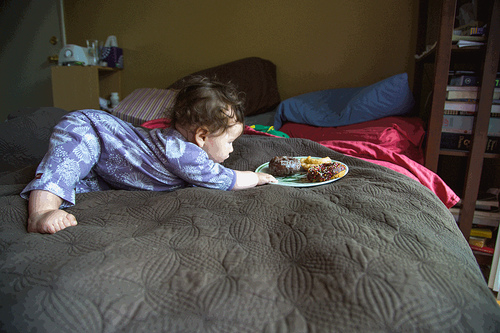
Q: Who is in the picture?
A: A baby.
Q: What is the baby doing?
A: Eating.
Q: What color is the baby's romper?
A: Blue.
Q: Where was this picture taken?
A: A bedroom.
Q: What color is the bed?
A: Grey.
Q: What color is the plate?
A: White.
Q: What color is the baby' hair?
A: Black.